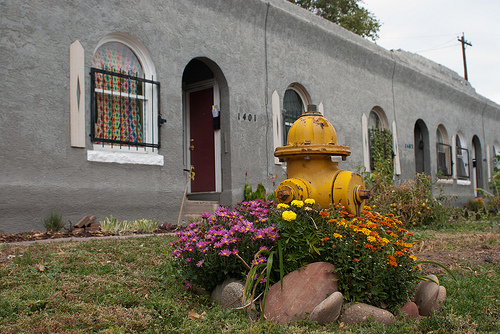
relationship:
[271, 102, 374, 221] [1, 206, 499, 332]
hydrant in yard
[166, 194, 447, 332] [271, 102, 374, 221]
garden around hydrant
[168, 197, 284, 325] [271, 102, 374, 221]
flowers next to hydrant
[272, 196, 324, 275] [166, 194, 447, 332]
marigolds in garden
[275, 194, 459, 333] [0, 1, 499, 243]
flowers in front of house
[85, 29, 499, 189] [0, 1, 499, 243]
windows on house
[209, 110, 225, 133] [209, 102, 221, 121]
mailbox full of mail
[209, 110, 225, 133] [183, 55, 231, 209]
mailbox on wall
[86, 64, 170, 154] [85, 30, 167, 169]
bars on window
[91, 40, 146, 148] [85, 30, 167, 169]
curtains seen in window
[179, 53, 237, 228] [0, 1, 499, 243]
archway in stone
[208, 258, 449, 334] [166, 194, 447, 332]
rocks around garden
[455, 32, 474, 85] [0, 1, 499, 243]
pole behind building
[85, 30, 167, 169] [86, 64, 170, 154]
window has bars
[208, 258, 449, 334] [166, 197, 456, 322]
rocks in front of flowers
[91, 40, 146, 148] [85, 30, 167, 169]
curtain in window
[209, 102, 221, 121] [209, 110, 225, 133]
mail in box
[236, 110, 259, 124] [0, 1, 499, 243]
numbers on house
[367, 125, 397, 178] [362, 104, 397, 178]
greenery covering window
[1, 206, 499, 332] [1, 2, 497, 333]
grass in front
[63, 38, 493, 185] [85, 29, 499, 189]
shutter near window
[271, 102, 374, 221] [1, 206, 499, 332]
hydrant on ground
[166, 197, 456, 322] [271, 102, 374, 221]
flowers are around hydrant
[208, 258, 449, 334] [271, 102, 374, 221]
rocks are around hydrant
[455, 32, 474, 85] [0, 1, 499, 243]
pole behind buildings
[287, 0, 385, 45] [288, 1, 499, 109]
leaves are in background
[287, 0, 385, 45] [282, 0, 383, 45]
leaves are from tree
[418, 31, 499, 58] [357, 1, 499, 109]
wires are in air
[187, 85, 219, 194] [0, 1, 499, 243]
door in building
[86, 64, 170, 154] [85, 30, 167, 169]
bars are over window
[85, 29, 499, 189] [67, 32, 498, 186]
widows have frames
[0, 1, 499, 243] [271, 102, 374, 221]
building behind hydrant